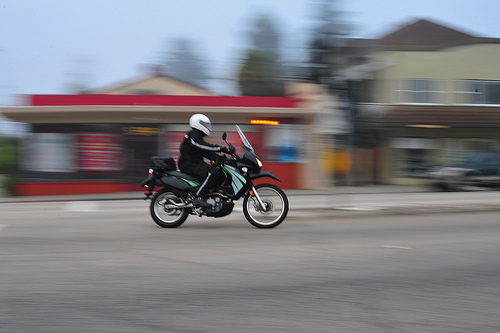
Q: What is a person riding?
A: A motorcycle.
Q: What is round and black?
A: Tires.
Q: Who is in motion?
A: Motorcycle and rider.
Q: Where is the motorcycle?
A: On the road.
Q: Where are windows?
A: On a building.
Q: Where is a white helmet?
A: On rider's head.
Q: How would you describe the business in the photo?
A: The business has multiple signs.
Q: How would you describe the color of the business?
A: Red.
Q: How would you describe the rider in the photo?
A: Rider wearing black clothing.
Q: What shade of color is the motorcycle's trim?
A: Green.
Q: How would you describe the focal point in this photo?
A: Man riding motorcycle quickly down road.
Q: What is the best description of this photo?
A: Man wearing white helmet riding motorcycle.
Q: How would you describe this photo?
A: Man riding a black bike with blue and green designs.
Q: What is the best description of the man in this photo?
A: Man on motorcycle wearing black jacket.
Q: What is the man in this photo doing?
A: Riding past red and brown store fast.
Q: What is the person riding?
A: A motorcycle.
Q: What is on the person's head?
A: Helmet.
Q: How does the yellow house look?
A: Blurry.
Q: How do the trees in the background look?
A: Blurry.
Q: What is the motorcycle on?
A: A street.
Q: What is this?
A: Motorcycle.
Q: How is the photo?
A: Blurry.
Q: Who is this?
A: Person.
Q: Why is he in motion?
A: Travelling.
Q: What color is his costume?
A: Black.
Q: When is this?
A: Daytime.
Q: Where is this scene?
A: Along a street.